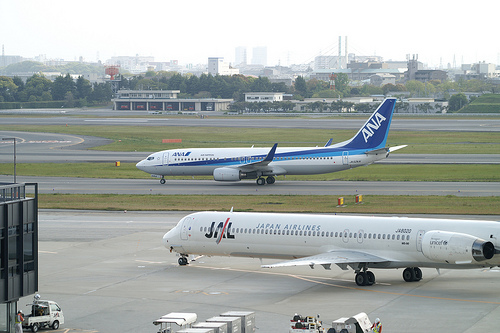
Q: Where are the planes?
A: Tarmac.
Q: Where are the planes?
A: Runway.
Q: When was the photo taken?
A: The day.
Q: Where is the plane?
A: Runway.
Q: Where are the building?
A: Background.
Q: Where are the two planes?
A: Runway.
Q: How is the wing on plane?
A: Tall.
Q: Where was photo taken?
A: Airport.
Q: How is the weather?
A: Overcast.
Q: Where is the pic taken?
A: Runway.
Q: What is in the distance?
A: A city.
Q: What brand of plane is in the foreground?
A: JAL.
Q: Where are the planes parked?
A: The tarmac.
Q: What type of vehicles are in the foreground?
A: White trucks.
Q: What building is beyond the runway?
A: An airport.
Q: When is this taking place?
A: Daytime.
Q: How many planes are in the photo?
A: Two.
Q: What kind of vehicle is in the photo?
A: Airplane.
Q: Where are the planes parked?
A: Cement tarmac.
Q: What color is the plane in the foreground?
A: White blue an red.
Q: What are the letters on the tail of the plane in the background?
A: ANA.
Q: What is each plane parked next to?
A: Strip of grass.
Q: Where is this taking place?
A: At the airport.